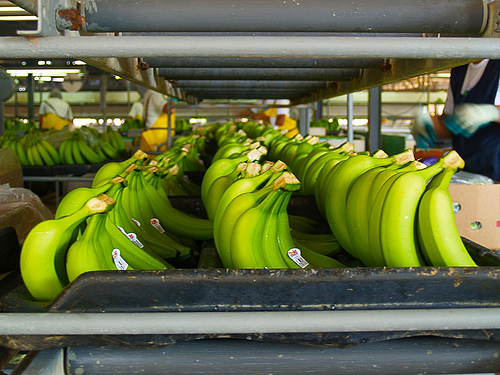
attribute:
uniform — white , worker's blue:
[446, 57, 498, 182]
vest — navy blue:
[449, 59, 499, 184]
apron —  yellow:
[145, 108, 176, 153]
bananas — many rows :
[369, 149, 477, 271]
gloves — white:
[395, 97, 497, 151]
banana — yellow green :
[18, 194, 114, 293]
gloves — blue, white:
[404, 94, 493, 151]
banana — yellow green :
[139, 133, 373, 254]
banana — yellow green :
[54, 183, 110, 225]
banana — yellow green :
[231, 176, 283, 270]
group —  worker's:
[38, 49, 497, 184]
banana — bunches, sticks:
[26, 184, 141, 281]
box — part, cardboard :
[438, 178, 499, 247]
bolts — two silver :
[448, 191, 488, 240]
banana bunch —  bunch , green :
[232, 173, 309, 268]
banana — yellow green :
[214, 171, 313, 271]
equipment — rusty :
[54, 3, 85, 32]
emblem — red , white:
[279, 242, 301, 259]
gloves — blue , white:
[433, 89, 495, 151]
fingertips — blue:
[440, 117, 470, 141]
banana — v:
[374, 142, 461, 252]